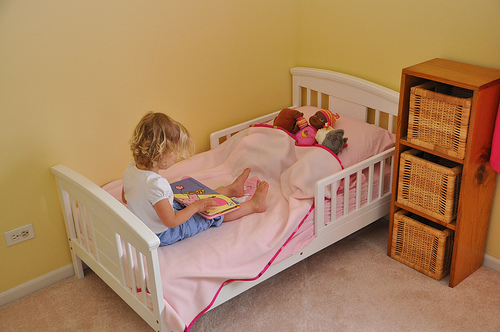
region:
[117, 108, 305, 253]
a child sitting on a bed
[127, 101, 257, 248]
a child reading a book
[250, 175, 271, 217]
a foot of a child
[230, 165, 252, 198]
a foot of a child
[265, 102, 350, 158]
several stuffed animals on pillow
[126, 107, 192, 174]
the head of a child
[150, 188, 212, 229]
the arm of a child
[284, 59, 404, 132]
the headboard of a bed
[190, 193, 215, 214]
the hand of a child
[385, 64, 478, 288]
a shelf with wicker baskets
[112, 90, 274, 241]
a young girl reads in her bed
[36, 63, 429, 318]
the girl sits on a toddler bed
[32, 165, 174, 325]
the girls bed is white in color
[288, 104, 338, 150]
a baby doll lays on the bed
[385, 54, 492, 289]
three organizing bins are next to the bed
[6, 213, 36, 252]
an electrical outlet is on the wall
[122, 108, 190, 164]
the girl has blonde curly hair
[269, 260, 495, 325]
the carpet appears to be light pink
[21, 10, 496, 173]
the walls are painted yellow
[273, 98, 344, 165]
the girl has some stuffed animals tucked in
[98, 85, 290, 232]
the girl is reading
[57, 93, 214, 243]
the girl is reading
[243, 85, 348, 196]
the toys are under the blanket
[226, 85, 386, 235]
the toys are under the blanket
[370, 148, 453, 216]
basket in the shelf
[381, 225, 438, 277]
basket in the shelf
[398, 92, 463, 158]
basket in the shelf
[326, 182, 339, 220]
bar on the bed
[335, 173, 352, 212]
bar on the bed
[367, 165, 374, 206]
bar on the bed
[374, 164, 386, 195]
bar on the bed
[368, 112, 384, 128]
bar on the bed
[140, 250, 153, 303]
bar on the bed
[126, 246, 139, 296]
bar on the bed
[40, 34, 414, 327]
a white kid bed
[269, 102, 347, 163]
flush toys and a doll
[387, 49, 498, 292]
a three level wooden shelf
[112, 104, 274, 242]
kid sitting on a bed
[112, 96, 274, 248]
kid wearing a white shirt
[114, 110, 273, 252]
kid is reading a book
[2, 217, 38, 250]
two power wall outlets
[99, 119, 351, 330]
a pink bed blanket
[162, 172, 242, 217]
a cute children's book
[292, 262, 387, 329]
soft beige carpet floor